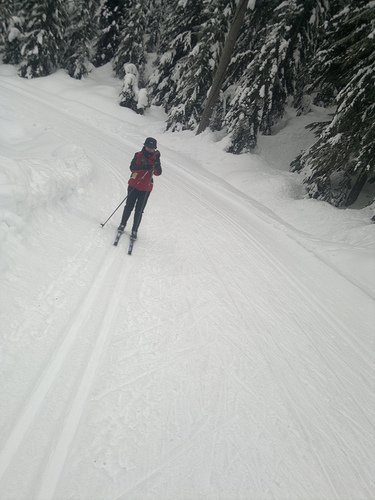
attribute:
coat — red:
[128, 151, 154, 191]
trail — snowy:
[80, 242, 366, 400]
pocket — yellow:
[129, 170, 138, 177]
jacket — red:
[123, 147, 166, 189]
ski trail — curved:
[4, 244, 133, 491]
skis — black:
[108, 208, 149, 253]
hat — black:
[131, 130, 162, 152]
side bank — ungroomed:
[3, 121, 91, 200]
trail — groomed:
[2, 65, 370, 498]